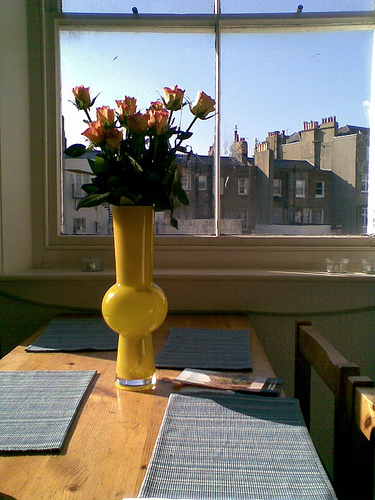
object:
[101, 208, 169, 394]
vase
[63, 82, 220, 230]
boquet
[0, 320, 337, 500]
table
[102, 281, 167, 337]
bulge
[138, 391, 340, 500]
placemat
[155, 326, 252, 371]
placemat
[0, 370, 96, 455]
placemat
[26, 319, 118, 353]
placemat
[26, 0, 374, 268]
window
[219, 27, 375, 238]
panel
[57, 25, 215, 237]
panel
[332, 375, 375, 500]
chairs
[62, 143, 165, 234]
buildings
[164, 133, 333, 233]
buildings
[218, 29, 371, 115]
sky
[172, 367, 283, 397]
pamphlet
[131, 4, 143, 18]
lock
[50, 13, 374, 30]
frame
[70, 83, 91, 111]
flower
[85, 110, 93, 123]
stem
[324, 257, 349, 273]
holder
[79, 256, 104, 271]
holder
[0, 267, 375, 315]
sill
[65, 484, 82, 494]
knot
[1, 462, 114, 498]
wood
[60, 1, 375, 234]
outside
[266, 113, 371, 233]
building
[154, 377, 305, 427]
shadow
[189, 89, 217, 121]
roses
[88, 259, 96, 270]
candle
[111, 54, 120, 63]
bird